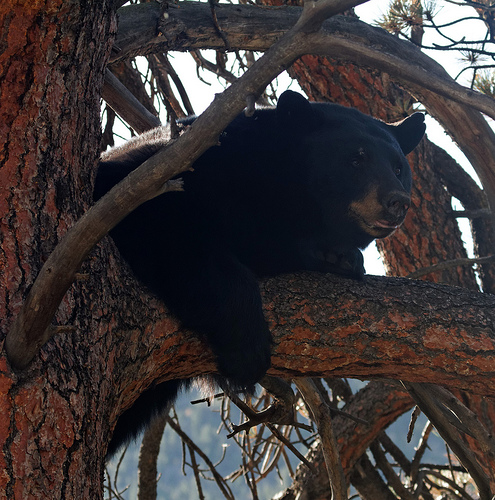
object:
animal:
[94, 88, 426, 394]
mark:
[359, 151, 365, 155]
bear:
[92, 89, 426, 389]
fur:
[177, 374, 216, 402]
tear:
[422, 115, 426, 125]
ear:
[386, 110, 426, 155]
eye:
[353, 160, 361, 167]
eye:
[393, 167, 400, 176]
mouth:
[363, 218, 402, 230]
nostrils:
[388, 194, 411, 217]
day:
[3, 0, 495, 500]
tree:
[0, 0, 495, 500]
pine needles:
[365, 0, 437, 51]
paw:
[206, 331, 272, 389]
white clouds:
[169, 403, 213, 444]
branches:
[95, 0, 495, 500]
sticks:
[0, 0, 106, 500]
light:
[185, 376, 218, 407]